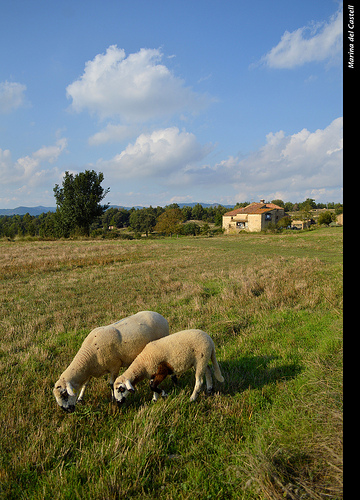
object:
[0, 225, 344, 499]
grass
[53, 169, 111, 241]
tree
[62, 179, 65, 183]
leaves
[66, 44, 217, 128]
cloud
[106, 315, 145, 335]
wool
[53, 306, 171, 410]
sheep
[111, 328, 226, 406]
sheep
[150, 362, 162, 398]
leg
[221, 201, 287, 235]
house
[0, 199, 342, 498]
field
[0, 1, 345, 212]
blue sky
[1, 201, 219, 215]
mountains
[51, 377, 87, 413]
head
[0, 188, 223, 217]
horizon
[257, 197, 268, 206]
chimney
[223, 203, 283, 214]
roof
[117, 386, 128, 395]
markings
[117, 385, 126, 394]
black markings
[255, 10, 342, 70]
cloud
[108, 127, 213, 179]
cloud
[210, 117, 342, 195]
cloud